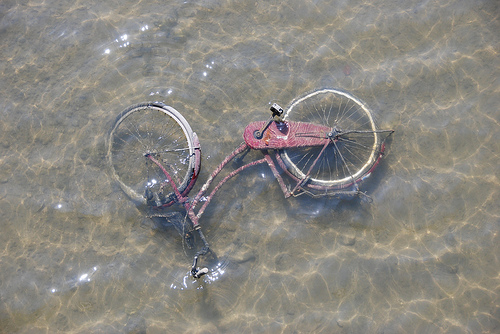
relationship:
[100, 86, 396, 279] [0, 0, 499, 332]
bicycle in water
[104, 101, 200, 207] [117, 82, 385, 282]
wheel on bicycle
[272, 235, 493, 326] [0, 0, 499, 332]
waves in water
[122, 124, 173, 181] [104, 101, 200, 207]
spokes in wheel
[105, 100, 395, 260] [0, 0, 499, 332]
bicycle in water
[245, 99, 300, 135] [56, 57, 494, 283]
pedal of bike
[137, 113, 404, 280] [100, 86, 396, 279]
frame of bicycle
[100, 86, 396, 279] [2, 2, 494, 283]
bicycle in water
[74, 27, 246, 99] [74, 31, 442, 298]
reflections from water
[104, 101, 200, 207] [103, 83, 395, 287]
wheel of bicycle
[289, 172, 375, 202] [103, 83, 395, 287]
fender of bicycle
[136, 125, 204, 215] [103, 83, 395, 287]
fender of bicycle